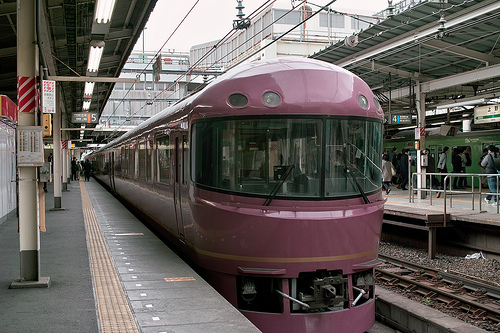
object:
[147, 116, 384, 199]
window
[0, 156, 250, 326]
platform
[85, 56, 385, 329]
train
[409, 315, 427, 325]
no objects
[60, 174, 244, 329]
concrete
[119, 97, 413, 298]
commuter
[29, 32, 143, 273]
depot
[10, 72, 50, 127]
red and white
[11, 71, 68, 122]
sign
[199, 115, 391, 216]
large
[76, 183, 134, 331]
yellow lines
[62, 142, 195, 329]
sidewalk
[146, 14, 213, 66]
gray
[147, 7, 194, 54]
in sky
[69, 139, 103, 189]
people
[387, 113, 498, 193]
train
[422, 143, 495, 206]
windsjile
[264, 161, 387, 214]
wipers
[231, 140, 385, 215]
glass window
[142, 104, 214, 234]
train door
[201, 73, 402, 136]
lights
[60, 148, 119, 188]
people waiting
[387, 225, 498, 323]
tracks next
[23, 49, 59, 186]
postings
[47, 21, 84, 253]
pillars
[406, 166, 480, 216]
safety rails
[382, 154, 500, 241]
platform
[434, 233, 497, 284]
trash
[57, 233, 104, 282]
part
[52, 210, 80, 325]
floor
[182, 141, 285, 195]
part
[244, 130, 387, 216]
window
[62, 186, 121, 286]
part of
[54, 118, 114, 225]
people standing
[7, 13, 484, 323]
picture taken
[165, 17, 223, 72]
day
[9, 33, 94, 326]
on post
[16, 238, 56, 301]
base of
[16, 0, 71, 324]
pillar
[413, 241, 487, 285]
gravel on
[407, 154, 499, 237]
metal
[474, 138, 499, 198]
person at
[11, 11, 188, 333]
station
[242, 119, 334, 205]
windshield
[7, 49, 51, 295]
on pole